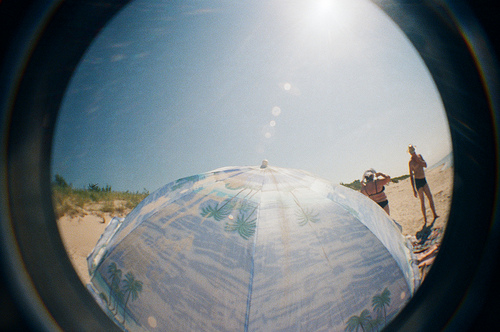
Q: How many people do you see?
A: 2.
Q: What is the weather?
A: Sunny.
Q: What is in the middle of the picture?
A: An umbrella.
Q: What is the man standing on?
A: Sand.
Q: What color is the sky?
A: Blue.